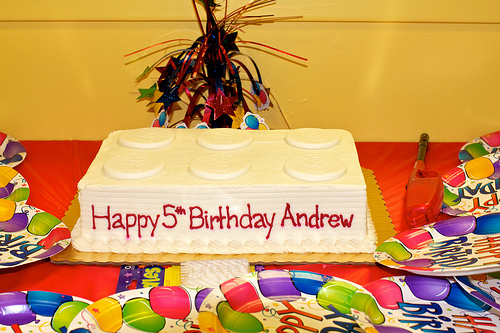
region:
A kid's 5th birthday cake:
[55, 112, 396, 274]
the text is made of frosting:
[85, 193, 369, 257]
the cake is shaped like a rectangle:
[70, 117, 379, 262]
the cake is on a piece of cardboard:
[40, 118, 407, 275]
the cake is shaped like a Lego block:
[45, 111, 421, 278]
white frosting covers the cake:
[61, 120, 406, 270]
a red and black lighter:
[399, 120, 456, 235]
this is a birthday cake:
[51, 103, 436, 269]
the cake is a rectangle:
[61, 115, 382, 260]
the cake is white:
[77, 90, 394, 265]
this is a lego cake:
[47, 81, 379, 261]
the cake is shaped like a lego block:
[47, 98, 387, 283]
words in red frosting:
[79, 189, 366, 249]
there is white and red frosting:
[83, 188, 364, 258]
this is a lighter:
[382, 114, 459, 236]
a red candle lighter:
[373, 106, 452, 238]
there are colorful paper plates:
[3, 103, 497, 328]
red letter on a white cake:
[335, 208, 357, 228]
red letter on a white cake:
[327, 212, 340, 230]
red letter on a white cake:
[316, 208, 331, 230]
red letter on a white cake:
[305, 202, 327, 229]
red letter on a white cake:
[294, 210, 311, 227]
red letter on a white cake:
[277, 198, 299, 230]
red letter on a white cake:
[261, 207, 278, 242]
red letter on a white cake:
[249, 208, 269, 230]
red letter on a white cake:
[237, 200, 254, 234]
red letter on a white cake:
[220, 202, 242, 230]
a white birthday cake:
[68, 113, 385, 259]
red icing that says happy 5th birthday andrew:
[87, 187, 366, 233]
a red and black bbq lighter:
[398, 112, 446, 237]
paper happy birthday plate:
[194, 249, 384, 331]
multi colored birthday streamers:
[129, 0, 297, 145]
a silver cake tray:
[52, 138, 405, 273]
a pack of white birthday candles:
[115, 254, 274, 288]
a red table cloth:
[4, 116, 465, 302]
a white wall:
[1, 19, 491, 138]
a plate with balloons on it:
[1, 193, 76, 274]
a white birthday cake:
[58, 114, 405, 274]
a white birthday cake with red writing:
[70, 121, 395, 260]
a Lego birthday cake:
[72, 122, 389, 259]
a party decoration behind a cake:
[122, 1, 317, 125]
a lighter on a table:
[403, 125, 445, 236]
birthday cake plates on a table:
[426, 125, 499, 330]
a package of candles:
[116, 254, 265, 290]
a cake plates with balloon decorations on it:
[204, 264, 387, 332]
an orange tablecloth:
[31, 138, 70, 205]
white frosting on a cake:
[111, 127, 323, 178]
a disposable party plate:
[201, 266, 360, 331]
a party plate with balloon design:
[71, 280, 211, 332]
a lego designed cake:
[58, 119, 370, 264]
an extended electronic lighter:
[401, 127, 454, 234]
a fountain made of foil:
[114, 3, 333, 137]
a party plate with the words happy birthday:
[376, 216, 498, 278]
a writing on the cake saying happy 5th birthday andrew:
[59, 188, 372, 263]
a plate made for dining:
[368, 211, 497, 286]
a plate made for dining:
[438, 151, 497, 224]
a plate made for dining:
[458, 132, 498, 160]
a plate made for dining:
[363, 268, 498, 331]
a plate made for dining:
[196, 277, 371, 332]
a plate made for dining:
[3, 161, 33, 211]